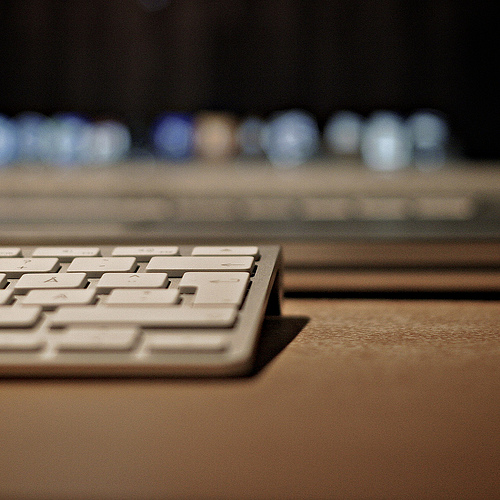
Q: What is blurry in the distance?
A: Objects.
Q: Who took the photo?
A: Jackson Mingus.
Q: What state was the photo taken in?
A: Ohio.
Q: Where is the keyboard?
A: In front of the photo.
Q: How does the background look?
A: Out of focus.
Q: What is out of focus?
A: Some keys.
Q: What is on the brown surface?
A: A computer keyboard.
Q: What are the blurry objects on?
A: A mantel.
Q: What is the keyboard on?
A: A table.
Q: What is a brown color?
A: The table.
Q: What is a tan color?
A: A keyboard.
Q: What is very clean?
A: The keyboard.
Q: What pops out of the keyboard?
A: The keys.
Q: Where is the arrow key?
A: On keyboard.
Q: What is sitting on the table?
A: Keyboard.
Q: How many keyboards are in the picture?
A: One.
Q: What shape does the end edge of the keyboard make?
A: Check.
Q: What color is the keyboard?
A: Gray.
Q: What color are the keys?
A: White.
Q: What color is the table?
A: Brown.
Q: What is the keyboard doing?
A: Sitting.